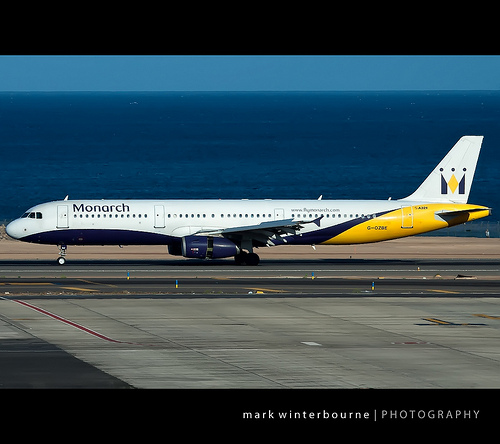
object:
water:
[3, 90, 499, 239]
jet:
[3, 127, 493, 270]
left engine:
[181, 235, 242, 260]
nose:
[2, 215, 29, 242]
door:
[55, 202, 71, 229]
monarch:
[72, 202, 132, 215]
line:
[3, 266, 493, 275]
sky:
[1, 54, 496, 95]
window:
[144, 213, 148, 219]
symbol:
[436, 163, 470, 199]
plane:
[5, 133, 490, 265]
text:
[239, 409, 482, 422]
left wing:
[191, 217, 310, 235]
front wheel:
[57, 256, 67, 266]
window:
[26, 211, 40, 218]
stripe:
[10, 295, 120, 344]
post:
[371, 281, 376, 292]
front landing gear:
[54, 241, 71, 265]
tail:
[410, 128, 490, 204]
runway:
[3, 253, 498, 299]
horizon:
[2, 84, 497, 98]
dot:
[436, 163, 445, 176]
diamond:
[448, 171, 460, 196]